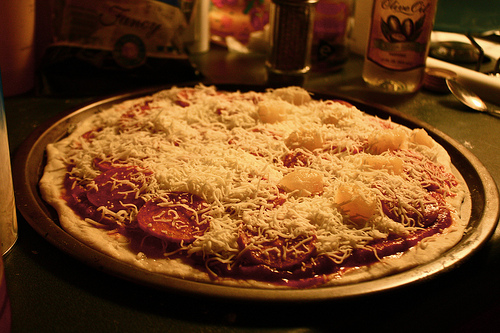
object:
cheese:
[334, 263, 364, 271]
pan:
[363, 262, 415, 281]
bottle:
[312, 2, 351, 66]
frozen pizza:
[38, 84, 474, 288]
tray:
[21, 79, 496, 302]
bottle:
[364, 2, 437, 92]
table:
[2, 78, 416, 250]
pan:
[75, 119, 106, 131]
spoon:
[444, 72, 489, 113]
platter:
[354, 89, 498, 299]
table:
[382, 65, 485, 140]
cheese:
[161, 173, 191, 192]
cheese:
[245, 172, 267, 177]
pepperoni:
[133, 200, 203, 240]